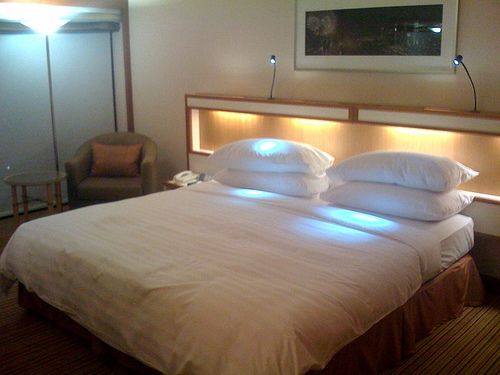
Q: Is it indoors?
A: Yes, it is indoors.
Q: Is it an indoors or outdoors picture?
A: It is indoors.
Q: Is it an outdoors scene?
A: No, it is indoors.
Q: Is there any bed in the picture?
A: Yes, there is a bed.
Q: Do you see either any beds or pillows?
A: Yes, there is a bed.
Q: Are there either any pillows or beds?
A: Yes, there is a bed.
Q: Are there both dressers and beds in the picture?
A: No, there is a bed but no dressers.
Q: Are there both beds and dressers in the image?
A: No, there is a bed but no dressers.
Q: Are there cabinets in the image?
A: No, there are no cabinets.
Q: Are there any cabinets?
A: No, there are no cabinets.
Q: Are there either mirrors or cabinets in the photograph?
A: No, there are no cabinets or mirrors.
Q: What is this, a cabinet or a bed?
A: This is a bed.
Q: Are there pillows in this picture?
A: Yes, there is a pillow.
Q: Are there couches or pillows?
A: Yes, there is a pillow.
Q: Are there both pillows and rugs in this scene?
A: Yes, there are both a pillow and a rug.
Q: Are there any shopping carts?
A: No, there are no shopping carts.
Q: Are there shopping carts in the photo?
A: No, there are no shopping carts.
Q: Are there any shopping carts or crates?
A: No, there are no shopping carts or crates.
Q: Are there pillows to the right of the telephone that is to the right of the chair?
A: Yes, there is a pillow to the right of the telephone.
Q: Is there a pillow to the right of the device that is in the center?
A: Yes, there is a pillow to the right of the telephone.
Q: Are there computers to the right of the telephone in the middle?
A: No, there is a pillow to the right of the telephone.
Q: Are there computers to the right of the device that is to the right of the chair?
A: No, there is a pillow to the right of the telephone.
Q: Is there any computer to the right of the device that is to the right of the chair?
A: No, there is a pillow to the right of the telephone.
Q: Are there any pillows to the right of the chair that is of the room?
A: Yes, there is a pillow to the right of the chair.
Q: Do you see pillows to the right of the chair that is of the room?
A: Yes, there is a pillow to the right of the chair.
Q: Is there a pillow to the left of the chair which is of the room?
A: No, the pillow is to the right of the chair.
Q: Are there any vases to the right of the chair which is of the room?
A: No, there is a pillow to the right of the chair.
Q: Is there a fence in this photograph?
A: No, there are no fences.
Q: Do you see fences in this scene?
A: No, there are no fences.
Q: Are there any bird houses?
A: No, there are no bird houses.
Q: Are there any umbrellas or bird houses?
A: No, there are no bird houses or umbrellas.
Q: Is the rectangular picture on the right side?
A: Yes, the picture is on the right of the image.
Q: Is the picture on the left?
A: No, the picture is on the right of the image.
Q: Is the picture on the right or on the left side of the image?
A: The picture is on the right of the image.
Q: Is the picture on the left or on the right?
A: The picture is on the right of the image.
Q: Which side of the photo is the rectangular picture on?
A: The picture is on the right of the image.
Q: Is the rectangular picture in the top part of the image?
A: Yes, the picture is in the top of the image.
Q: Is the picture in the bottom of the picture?
A: No, the picture is in the top of the image.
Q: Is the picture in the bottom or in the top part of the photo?
A: The picture is in the top of the image.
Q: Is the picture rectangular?
A: Yes, the picture is rectangular.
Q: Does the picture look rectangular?
A: Yes, the picture is rectangular.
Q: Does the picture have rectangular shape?
A: Yes, the picture is rectangular.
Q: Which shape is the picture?
A: The picture is rectangular.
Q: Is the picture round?
A: No, the picture is rectangular.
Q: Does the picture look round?
A: No, the picture is rectangular.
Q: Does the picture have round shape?
A: No, the picture is rectangular.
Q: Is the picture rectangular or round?
A: The picture is rectangular.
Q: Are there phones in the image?
A: Yes, there is a phone.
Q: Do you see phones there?
A: Yes, there is a phone.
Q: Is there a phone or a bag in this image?
A: Yes, there is a phone.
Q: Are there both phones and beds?
A: Yes, there are both a phone and a bed.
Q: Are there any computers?
A: No, there are no computers.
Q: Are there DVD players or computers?
A: No, there are no computers or DVD players.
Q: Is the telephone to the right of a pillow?
A: No, the telephone is to the left of a pillow.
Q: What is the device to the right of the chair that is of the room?
A: The device is a phone.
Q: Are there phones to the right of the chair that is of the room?
A: Yes, there is a phone to the right of the chair.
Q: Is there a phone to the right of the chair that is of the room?
A: Yes, there is a phone to the right of the chair.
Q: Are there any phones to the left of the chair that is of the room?
A: No, the phone is to the right of the chair.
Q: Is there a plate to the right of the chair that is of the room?
A: No, there is a phone to the right of the chair.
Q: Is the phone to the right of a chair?
A: Yes, the phone is to the right of a chair.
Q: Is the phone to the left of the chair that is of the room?
A: No, the phone is to the right of the chair.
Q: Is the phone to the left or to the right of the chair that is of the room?
A: The phone is to the right of the chair.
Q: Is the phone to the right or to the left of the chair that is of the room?
A: The phone is to the right of the chair.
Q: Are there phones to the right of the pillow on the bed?
A: Yes, there is a phone to the right of the pillow.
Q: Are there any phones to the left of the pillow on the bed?
A: No, the phone is to the right of the pillow.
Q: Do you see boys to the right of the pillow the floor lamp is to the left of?
A: No, there is a phone to the right of the pillow.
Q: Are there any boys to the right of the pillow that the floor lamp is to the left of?
A: No, there is a phone to the right of the pillow.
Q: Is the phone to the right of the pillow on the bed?
A: Yes, the phone is to the right of the pillow.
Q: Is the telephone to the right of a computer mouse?
A: No, the telephone is to the right of the pillow.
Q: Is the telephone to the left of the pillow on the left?
A: No, the telephone is to the right of the pillow.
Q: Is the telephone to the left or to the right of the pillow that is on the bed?
A: The telephone is to the right of the pillow.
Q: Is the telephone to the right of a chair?
A: Yes, the telephone is to the right of a chair.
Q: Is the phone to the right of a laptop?
A: No, the phone is to the right of a chair.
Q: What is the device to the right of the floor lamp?
A: The device is a phone.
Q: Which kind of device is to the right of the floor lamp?
A: The device is a phone.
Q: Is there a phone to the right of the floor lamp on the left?
A: Yes, there is a phone to the right of the floor lamp.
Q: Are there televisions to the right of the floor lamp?
A: No, there is a phone to the right of the floor lamp.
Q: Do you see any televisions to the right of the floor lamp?
A: No, there is a phone to the right of the floor lamp.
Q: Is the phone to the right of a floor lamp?
A: Yes, the phone is to the right of a floor lamp.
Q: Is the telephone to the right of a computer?
A: No, the telephone is to the right of a floor lamp.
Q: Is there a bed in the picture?
A: Yes, there is a bed.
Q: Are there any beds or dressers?
A: Yes, there is a bed.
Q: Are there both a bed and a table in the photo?
A: Yes, there are both a bed and a table.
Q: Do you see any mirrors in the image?
A: No, there are no mirrors.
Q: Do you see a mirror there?
A: No, there are no mirrors.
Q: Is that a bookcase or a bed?
A: That is a bed.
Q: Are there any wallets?
A: No, there are no wallets.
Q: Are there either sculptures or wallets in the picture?
A: No, there are no wallets or sculptures.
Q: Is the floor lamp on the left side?
A: Yes, the floor lamp is on the left of the image.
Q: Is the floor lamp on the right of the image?
A: No, the floor lamp is on the left of the image.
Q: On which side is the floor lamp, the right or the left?
A: The floor lamp is on the left of the image.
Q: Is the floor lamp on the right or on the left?
A: The floor lamp is on the left of the image.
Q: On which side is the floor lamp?
A: The floor lamp is on the left of the image.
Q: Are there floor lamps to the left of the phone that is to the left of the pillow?
A: Yes, there is a floor lamp to the left of the phone.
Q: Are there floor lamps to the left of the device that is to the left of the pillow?
A: Yes, there is a floor lamp to the left of the phone.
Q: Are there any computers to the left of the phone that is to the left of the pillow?
A: No, there is a floor lamp to the left of the phone.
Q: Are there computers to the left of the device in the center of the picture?
A: No, there is a floor lamp to the left of the phone.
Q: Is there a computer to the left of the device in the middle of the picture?
A: No, there is a floor lamp to the left of the phone.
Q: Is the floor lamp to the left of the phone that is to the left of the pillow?
A: Yes, the floor lamp is to the left of the phone.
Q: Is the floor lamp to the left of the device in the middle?
A: Yes, the floor lamp is to the left of the phone.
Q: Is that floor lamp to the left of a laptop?
A: No, the floor lamp is to the left of the phone.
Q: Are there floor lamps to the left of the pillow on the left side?
A: Yes, there is a floor lamp to the left of the pillow.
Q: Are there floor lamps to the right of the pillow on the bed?
A: No, the floor lamp is to the left of the pillow.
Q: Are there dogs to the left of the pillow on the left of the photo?
A: No, there is a floor lamp to the left of the pillow.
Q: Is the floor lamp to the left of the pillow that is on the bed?
A: Yes, the floor lamp is to the left of the pillow.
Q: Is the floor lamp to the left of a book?
A: No, the floor lamp is to the left of the pillow.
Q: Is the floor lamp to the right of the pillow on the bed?
A: No, the floor lamp is to the left of the pillow.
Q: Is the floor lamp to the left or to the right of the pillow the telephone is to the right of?
A: The floor lamp is to the left of the pillow.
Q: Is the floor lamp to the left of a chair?
A: Yes, the floor lamp is to the left of a chair.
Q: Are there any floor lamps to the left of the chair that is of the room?
A: Yes, there is a floor lamp to the left of the chair.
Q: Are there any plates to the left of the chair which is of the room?
A: No, there is a floor lamp to the left of the chair.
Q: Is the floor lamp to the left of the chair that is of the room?
A: Yes, the floor lamp is to the left of the chair.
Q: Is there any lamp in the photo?
A: Yes, there is a lamp.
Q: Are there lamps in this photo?
A: Yes, there is a lamp.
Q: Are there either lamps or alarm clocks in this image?
A: Yes, there is a lamp.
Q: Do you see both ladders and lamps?
A: No, there is a lamp but no ladders.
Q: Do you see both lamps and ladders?
A: No, there is a lamp but no ladders.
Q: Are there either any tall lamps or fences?
A: Yes, there is a tall lamp.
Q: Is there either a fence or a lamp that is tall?
A: Yes, the lamp is tall.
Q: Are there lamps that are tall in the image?
A: Yes, there is a tall lamp.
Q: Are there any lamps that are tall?
A: Yes, there is a lamp that is tall.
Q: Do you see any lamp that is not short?
A: Yes, there is a tall lamp.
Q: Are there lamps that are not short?
A: Yes, there is a tall lamp.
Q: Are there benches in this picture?
A: No, there are no benches.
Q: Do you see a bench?
A: No, there are no benches.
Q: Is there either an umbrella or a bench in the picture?
A: No, there are no benches or umbrellas.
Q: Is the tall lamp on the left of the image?
A: Yes, the lamp is on the left of the image.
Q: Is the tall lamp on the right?
A: No, the lamp is on the left of the image.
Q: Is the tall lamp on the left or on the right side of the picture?
A: The lamp is on the left of the image.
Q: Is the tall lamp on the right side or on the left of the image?
A: The lamp is on the left of the image.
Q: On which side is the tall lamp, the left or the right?
A: The lamp is on the left of the image.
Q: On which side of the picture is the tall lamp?
A: The lamp is on the left of the image.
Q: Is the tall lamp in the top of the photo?
A: Yes, the lamp is in the top of the image.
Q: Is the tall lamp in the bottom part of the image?
A: No, the lamp is in the top of the image.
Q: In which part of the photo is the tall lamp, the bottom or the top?
A: The lamp is in the top of the image.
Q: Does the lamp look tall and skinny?
A: Yes, the lamp is tall and skinny.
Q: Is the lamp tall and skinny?
A: Yes, the lamp is tall and skinny.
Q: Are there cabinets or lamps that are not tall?
A: No, there is a lamp but it is tall.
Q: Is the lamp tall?
A: Yes, the lamp is tall.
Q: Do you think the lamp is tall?
A: Yes, the lamp is tall.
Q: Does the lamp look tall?
A: Yes, the lamp is tall.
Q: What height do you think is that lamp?
A: The lamp is tall.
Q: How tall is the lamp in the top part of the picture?
A: The lamp is tall.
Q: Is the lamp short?
A: No, the lamp is tall.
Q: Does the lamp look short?
A: No, the lamp is tall.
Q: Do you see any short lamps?
A: No, there is a lamp but it is tall.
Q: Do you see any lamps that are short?
A: No, there is a lamp but it is tall.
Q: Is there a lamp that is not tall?
A: No, there is a lamp but it is tall.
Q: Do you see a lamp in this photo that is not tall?
A: No, there is a lamp but it is tall.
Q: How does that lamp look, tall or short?
A: The lamp is tall.